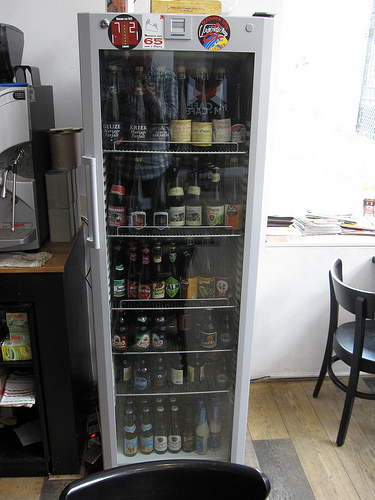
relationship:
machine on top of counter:
[1, 114, 78, 261] [1, 244, 69, 273]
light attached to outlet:
[86, 423, 97, 440] [75, 401, 101, 469]